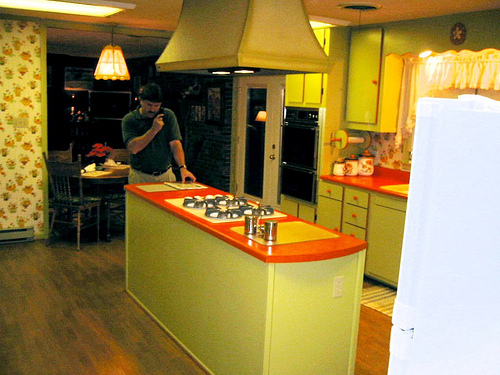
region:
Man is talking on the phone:
[131, 73, 171, 131]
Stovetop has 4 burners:
[181, 185, 273, 223]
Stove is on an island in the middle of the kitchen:
[113, 183, 370, 370]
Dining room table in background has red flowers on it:
[86, 142, 117, 178]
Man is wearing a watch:
[178, 158, 190, 175]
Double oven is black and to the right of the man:
[276, 106, 326, 218]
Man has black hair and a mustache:
[139, 80, 161, 122]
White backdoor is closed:
[232, 75, 299, 209]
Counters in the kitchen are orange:
[113, 163, 413, 290]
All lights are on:
[88, 16, 135, 86]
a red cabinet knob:
[351, 191, 360, 201]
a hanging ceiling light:
[94, 28, 131, 81]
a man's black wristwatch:
[175, 160, 190, 170]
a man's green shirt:
[122, 111, 182, 171]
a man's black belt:
[127, 165, 173, 177]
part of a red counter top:
[328, 160, 405, 196]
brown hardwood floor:
[0, 230, 209, 373]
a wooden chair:
[36, 141, 106, 248]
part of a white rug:
[352, 279, 398, 318]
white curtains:
[417, 50, 497, 89]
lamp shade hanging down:
[91, 38, 128, 82]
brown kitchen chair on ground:
[38, 155, 97, 253]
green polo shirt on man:
[121, 110, 181, 178]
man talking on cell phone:
[126, 86, 175, 145]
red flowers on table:
[84, 143, 114, 160]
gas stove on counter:
[192, 188, 254, 218]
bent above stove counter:
[171, 60, 298, 81]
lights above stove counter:
[206, 66, 253, 76]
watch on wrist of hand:
[171, 159, 188, 173]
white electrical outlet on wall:
[328, 272, 350, 299]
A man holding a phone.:
[121, 83, 196, 185]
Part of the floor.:
[72, 308, 134, 350]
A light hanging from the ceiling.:
[89, 42, 131, 84]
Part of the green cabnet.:
[357, 43, 371, 72]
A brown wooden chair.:
[40, 153, 102, 250]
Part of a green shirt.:
[149, 150, 163, 164]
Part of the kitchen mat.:
[374, 293, 388, 308]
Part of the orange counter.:
[359, 175, 376, 185]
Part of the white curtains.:
[426, 65, 485, 79]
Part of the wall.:
[7, 120, 29, 174]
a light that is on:
[91, 24, 129, 84]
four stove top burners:
[183, 188, 269, 218]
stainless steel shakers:
[242, 211, 277, 242]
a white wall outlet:
[333, 273, 344, 297]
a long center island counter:
[121, 178, 368, 372]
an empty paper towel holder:
[327, 127, 372, 149]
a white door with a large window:
[238, 79, 276, 209]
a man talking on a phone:
[122, 83, 195, 184]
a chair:
[38, 151, 104, 248]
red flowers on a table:
[84, 141, 110, 171]